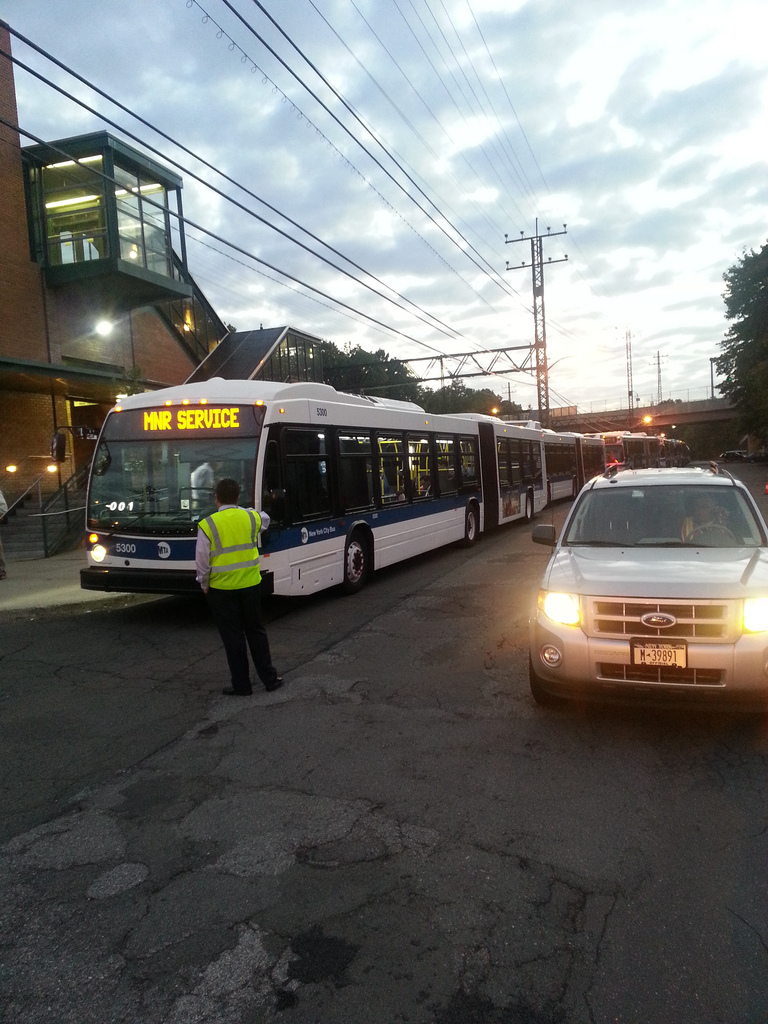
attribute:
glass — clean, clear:
[404, 451, 436, 501]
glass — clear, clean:
[460, 451, 479, 484]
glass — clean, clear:
[336, 430, 375, 455]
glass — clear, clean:
[434, 435, 456, 453]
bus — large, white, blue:
[76, 375, 545, 601]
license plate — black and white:
[627, 639, 687, 669]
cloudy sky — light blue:
[206, 43, 676, 306]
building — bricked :
[3, 21, 262, 544]